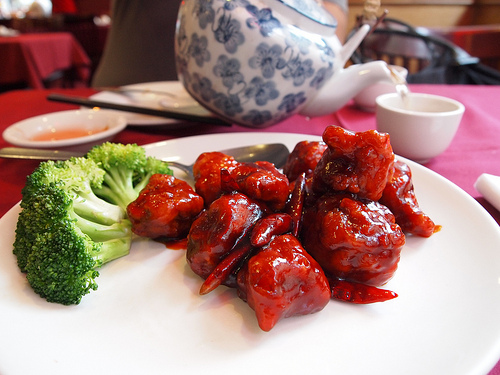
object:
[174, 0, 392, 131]
tea pot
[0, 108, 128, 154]
bowl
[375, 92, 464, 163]
teacup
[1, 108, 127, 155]
dish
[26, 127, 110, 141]
sauce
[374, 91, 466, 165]
cup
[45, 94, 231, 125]
chpsticks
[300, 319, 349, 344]
plate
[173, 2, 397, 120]
tea pot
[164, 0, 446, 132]
teapot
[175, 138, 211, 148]
plate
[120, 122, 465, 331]
wings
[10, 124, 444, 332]
food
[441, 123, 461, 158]
ground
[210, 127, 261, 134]
ground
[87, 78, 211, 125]
white plate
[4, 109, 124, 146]
white plate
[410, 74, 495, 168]
tablecloth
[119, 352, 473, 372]
plate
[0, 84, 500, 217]
tablecloth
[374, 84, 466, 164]
tea cup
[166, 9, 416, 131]
teapot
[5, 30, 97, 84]
tablecloth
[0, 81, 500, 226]
table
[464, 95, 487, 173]
tablecloth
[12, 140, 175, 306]
broccoli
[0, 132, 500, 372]
white plate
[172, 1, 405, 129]
teapot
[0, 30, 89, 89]
table cloth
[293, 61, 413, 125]
white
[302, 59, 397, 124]
spout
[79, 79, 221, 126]
plate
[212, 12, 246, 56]
flower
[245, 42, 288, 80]
flower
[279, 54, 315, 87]
flower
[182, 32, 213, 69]
flower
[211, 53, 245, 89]
flower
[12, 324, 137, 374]
plate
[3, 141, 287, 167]
silver spoon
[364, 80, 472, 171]
tea cup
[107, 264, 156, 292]
plate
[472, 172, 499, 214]
napkin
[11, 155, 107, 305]
broccoli head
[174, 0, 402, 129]
kettle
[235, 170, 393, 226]
meat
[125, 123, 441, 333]
chicken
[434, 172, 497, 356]
white plate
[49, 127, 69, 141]
liquid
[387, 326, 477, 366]
plate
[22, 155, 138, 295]
trees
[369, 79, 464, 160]
teacup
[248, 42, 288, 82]
floral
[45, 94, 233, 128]
chopsticks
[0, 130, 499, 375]
plate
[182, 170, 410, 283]
sauce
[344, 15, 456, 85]
chair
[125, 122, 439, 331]
sauce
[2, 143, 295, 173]
spoon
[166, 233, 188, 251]
sauce